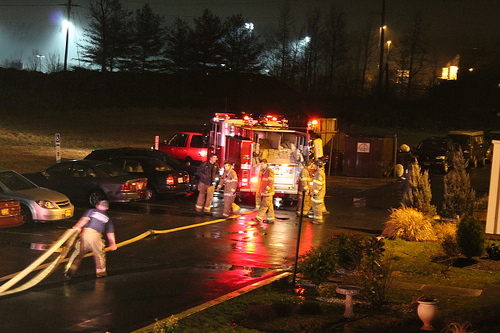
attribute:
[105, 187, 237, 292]
hose — long, yellow, fire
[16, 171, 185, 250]
cars — parked, red, silver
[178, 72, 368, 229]
truck — fire, red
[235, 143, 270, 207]
light — red, bright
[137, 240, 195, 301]
ground — wet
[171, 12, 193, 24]
sky — black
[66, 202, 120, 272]
man — holding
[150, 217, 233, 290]
street — wet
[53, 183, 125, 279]
fighter — fire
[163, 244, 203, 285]
bath — concrete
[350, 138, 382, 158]
sign — white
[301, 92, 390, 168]
dumpster — large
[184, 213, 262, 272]
road — wet